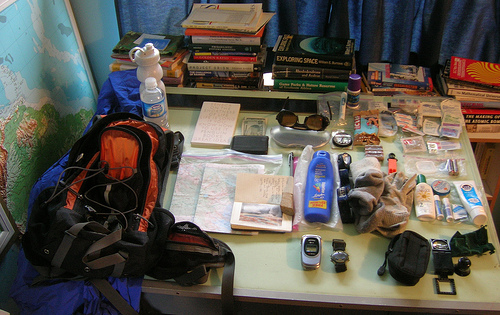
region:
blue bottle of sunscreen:
[303, 150, 340, 220]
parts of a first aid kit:
[391, 93, 468, 158]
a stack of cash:
[240, 113, 269, 145]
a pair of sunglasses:
[276, 93, 333, 132]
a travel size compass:
[431, 237, 458, 298]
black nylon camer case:
[381, 229, 433, 285]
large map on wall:
[2, 0, 102, 205]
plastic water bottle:
[136, 75, 170, 130]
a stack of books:
[178, 0, 266, 92]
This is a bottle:
[295, 141, 341, 252]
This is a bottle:
[121, 25, 192, 160]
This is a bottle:
[143, 73, 196, 171]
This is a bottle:
[344, 65, 371, 127]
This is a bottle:
[379, 138, 402, 176]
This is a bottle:
[404, 167, 436, 229]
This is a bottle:
[454, 178, 496, 243]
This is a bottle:
[381, 142, 413, 187]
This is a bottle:
[337, 64, 363, 116]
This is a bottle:
[412, 56, 435, 94]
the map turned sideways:
[0, 0, 99, 238]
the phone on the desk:
[300, 234, 322, 268]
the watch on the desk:
[330, 238, 349, 272]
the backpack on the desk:
[22, 113, 234, 314]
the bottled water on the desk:
[140, 77, 172, 132]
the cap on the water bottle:
[144, 77, 157, 89]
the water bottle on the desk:
[127, 42, 168, 122]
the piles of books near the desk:
[109, 3, 499, 133]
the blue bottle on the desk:
[303, 149, 333, 222]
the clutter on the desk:
[9, 41, 494, 313]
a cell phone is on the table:
[299, 234, 322, 271]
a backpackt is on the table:
[54, 112, 181, 262]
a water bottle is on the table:
[135, 78, 171, 128]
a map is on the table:
[166, 147, 288, 242]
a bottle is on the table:
[413, 175, 433, 220]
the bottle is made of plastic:
[410, 171, 435, 221]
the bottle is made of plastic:
[136, 77, 170, 130]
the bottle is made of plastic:
[306, 147, 331, 224]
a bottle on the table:
[140, 74, 172, 141]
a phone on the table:
[296, 232, 322, 269]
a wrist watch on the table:
[328, 239, 350, 276]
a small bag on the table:
[378, 231, 434, 286]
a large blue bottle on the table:
[303, 142, 335, 226]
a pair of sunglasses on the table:
[275, 93, 333, 132]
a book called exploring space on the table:
[269, 32, 360, 69]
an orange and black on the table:
[22, 112, 237, 314]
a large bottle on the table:
[125, 42, 172, 127]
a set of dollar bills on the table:
[240, 115, 271, 138]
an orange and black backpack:
[22, 110, 235, 313]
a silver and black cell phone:
[300, 232, 322, 269]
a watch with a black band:
[331, 237, 350, 273]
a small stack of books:
[270, 32, 355, 92]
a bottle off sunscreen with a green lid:
[415, 172, 435, 222]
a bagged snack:
[353, 108, 381, 145]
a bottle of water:
[140, 76, 170, 131]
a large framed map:
[0, 0, 99, 236]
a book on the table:
[281, 37, 298, 66]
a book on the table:
[286, 53, 345, 107]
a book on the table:
[215, 37, 265, 67]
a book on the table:
[152, 8, 239, 65]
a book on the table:
[431, 92, 495, 129]